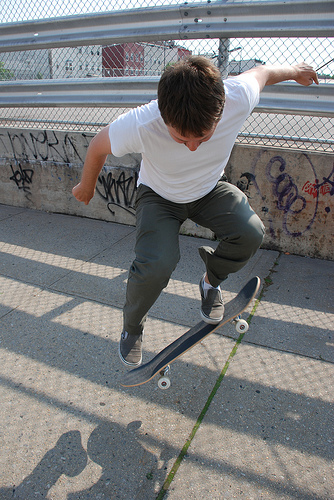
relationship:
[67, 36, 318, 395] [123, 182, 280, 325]
boy wearing pants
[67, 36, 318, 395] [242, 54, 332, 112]
boy has left arm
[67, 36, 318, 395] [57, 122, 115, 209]
boy has right arm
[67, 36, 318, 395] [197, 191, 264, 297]
boy has left leg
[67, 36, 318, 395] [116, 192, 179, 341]
boy has right leg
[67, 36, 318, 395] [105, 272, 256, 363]
boy wearing shoes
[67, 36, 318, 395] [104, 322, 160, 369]
boy has right foot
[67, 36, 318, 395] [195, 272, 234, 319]
boy has left foot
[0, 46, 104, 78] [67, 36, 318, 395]
building behind boy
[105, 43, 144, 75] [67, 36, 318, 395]
building behind boy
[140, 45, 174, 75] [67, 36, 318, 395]
building behind boy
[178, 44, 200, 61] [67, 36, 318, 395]
building behind boy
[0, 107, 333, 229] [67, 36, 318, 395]
wall behind boy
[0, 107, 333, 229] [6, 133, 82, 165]
wall has graffiti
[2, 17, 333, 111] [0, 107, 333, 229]
railing on top of wall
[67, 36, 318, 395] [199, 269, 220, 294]
boy wearing sock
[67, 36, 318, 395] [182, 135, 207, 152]
boy has nose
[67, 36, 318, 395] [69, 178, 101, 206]
boy has right hand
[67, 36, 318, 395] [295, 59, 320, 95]
boy has left hand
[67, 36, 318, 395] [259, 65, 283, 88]
boy has elbow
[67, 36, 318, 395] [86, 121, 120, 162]
boy has elbow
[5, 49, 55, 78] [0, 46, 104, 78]
wall of building